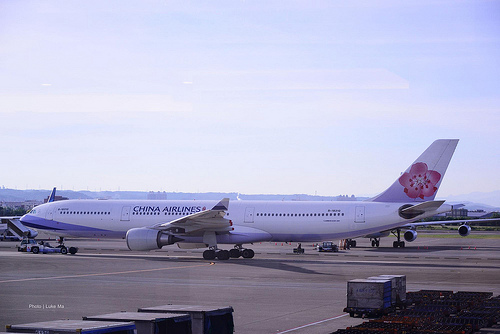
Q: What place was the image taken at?
A: It was taken at the airport.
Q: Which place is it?
A: It is an airport.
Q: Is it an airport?
A: Yes, it is an airport.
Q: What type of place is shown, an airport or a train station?
A: It is an airport.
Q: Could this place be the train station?
A: No, it is the airport.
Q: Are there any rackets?
A: No, there are no rackets.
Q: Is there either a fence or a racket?
A: No, there are no rackets or fences.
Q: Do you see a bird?
A: No, there are no birds.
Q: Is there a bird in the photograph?
A: No, there are no birds.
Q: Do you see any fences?
A: No, there are no fences.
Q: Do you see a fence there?
A: No, there are no fences.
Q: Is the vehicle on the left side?
A: Yes, the vehicle is on the left of the image.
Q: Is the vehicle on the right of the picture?
A: No, the vehicle is on the left of the image.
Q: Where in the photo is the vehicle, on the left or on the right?
A: The vehicle is on the left of the image.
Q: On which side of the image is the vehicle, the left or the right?
A: The vehicle is on the left of the image.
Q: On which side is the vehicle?
A: The vehicle is on the left of the image.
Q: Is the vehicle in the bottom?
A: Yes, the vehicle is in the bottom of the image.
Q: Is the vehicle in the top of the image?
A: No, the vehicle is in the bottom of the image.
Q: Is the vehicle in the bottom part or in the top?
A: The vehicle is in the bottom of the image.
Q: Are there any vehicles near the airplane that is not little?
A: Yes, there is a vehicle near the plane.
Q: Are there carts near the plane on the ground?
A: No, there is a vehicle near the airplane.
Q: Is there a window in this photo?
A: Yes, there are windows.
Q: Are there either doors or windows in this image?
A: Yes, there are windows.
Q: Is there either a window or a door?
A: Yes, there are windows.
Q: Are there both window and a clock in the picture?
A: No, there are windows but no clocks.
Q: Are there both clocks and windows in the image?
A: No, there are windows but no clocks.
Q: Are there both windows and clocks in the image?
A: No, there are windows but no clocks.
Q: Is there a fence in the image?
A: No, there are no fences.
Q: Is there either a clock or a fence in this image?
A: No, there are no fences or clocks.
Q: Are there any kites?
A: No, there are no kites.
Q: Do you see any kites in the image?
A: No, there are no kites.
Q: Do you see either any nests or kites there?
A: No, there are no kites or nests.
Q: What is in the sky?
A: The clouds are in the sky.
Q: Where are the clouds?
A: The clouds are in the sky.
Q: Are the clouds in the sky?
A: Yes, the clouds are in the sky.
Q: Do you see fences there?
A: No, there are no fences.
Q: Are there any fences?
A: No, there are no fences.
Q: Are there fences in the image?
A: No, there are no fences.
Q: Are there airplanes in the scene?
A: Yes, there is an airplane.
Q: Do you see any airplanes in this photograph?
A: Yes, there is an airplane.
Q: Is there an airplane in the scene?
A: Yes, there is an airplane.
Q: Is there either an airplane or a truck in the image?
A: Yes, there is an airplane.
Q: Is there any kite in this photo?
A: No, there are no kites.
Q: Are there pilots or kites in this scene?
A: No, there are no kites or pilots.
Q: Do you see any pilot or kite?
A: No, there are no kites or pilots.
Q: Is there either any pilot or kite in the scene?
A: No, there are no kites or pilots.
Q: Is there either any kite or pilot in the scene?
A: No, there are no kites or pilots.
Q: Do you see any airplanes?
A: Yes, there is an airplane.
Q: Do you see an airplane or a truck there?
A: Yes, there is an airplane.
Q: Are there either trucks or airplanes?
A: Yes, there is an airplane.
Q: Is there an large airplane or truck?
A: Yes, there is a large airplane.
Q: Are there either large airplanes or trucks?
A: Yes, there is a large airplane.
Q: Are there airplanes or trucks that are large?
A: Yes, the airplane is large.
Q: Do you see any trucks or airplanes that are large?
A: Yes, the airplane is large.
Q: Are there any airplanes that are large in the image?
A: Yes, there is a large airplane.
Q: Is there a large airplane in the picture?
A: Yes, there is a large airplane.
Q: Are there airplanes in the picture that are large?
A: Yes, there is an airplane that is large.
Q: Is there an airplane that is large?
A: Yes, there is an airplane that is large.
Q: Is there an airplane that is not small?
A: Yes, there is a large airplane.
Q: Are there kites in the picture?
A: No, there are no kites.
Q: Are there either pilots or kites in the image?
A: No, there are no kites or pilots.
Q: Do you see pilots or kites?
A: No, there are no kites or pilots.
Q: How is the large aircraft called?
A: The aircraft is an airplane.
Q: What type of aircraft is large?
A: The aircraft is an airplane.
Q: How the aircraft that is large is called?
A: The aircraft is an airplane.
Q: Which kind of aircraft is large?
A: The aircraft is an airplane.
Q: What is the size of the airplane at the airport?
A: The plane is large.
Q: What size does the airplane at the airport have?
A: The plane has large size.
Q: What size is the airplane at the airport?
A: The plane is large.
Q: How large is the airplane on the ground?
A: The airplane is large.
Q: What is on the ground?
A: The plane is on the ground.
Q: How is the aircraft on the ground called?
A: The aircraft is an airplane.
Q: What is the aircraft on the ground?
A: The aircraft is an airplane.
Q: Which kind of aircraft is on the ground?
A: The aircraft is an airplane.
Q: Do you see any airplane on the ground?
A: Yes, there is an airplane on the ground.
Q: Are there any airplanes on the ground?
A: Yes, there is an airplane on the ground.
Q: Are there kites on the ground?
A: No, there is an airplane on the ground.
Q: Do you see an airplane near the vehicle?
A: Yes, there is an airplane near the vehicle.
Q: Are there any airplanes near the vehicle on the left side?
A: Yes, there is an airplane near the vehicle.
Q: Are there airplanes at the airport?
A: Yes, there is an airplane at the airport.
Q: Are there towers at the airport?
A: No, there is an airplane at the airport.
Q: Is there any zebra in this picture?
A: No, there are no zebras.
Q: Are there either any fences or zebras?
A: No, there are no zebras or fences.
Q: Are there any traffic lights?
A: No, there are no traffic lights.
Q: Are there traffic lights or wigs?
A: No, there are no traffic lights or wigs.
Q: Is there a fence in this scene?
A: No, there are no fences.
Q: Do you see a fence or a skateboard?
A: No, there are no fences or skateboards.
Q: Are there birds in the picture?
A: No, there are no birds.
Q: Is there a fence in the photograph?
A: No, there are no fences.